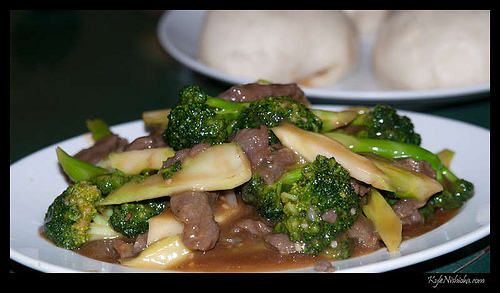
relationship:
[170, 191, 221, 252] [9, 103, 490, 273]
beef on a plate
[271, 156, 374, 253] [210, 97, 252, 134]
broccoli has stem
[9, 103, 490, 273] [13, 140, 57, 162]
plate has an edge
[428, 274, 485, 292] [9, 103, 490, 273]
graphic under plate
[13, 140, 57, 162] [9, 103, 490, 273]
edge of a plate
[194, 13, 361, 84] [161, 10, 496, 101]
dough ball on plate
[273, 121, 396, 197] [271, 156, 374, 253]
bamboo shoot on top of broccoli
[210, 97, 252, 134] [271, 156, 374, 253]
stem of broccoli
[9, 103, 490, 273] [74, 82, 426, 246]
plate filled with food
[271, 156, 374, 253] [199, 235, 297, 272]
broccoli covered in sauce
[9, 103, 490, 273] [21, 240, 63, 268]
plate has reflection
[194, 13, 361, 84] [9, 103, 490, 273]
dough ball on plate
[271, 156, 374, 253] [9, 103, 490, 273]
broccoli on top of plate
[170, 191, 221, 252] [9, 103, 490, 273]
beef on plate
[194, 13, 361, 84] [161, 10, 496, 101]
dough ball on a plate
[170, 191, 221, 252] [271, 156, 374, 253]
beef and broccoli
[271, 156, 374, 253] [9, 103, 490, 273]
broccoli on plate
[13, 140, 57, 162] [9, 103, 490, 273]
edge of plate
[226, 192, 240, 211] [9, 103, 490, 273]
onion on plate